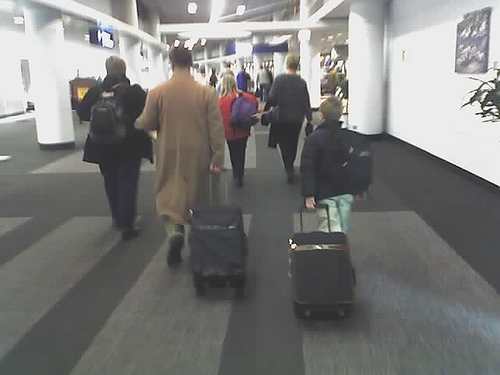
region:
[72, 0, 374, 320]
people carrying suitcases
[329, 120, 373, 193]
a boy carrying a black backpack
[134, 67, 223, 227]
man wearing a long light brown coat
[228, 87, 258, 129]
woman carrying a purple backpack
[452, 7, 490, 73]
a black and white poster on the wall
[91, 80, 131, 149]
a woman carrying a black backpack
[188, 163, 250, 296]
man carrying a black suitcase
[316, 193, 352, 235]
boy wearing light green pants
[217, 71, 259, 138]
a blonde woman wearing a red coat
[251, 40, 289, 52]
a purple banner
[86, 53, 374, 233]
the backs of a group of people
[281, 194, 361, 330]
a black suitcase on wheels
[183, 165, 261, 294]
a gray suitcase on wheels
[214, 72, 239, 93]
the head of a person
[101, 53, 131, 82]
the head of a person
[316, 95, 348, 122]
the head of a person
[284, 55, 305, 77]
the head of a person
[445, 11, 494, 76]
a picture on a wall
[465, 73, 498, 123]
the leaves of a plant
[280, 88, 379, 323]
a boy pulling a suitcase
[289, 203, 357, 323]
a black rolling luggage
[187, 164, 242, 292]
a black rolling luggage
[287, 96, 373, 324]
a child pulling luggage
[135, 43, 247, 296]
a man pulling luggage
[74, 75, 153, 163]
a black winter coat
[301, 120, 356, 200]
a black winter coat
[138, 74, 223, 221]
a long brown coat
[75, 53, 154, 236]
a woman with backpack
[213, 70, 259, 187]
a woman with purple backpack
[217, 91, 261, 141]
a red winter coat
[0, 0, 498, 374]
People walking in the hallway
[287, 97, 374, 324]
The kid dragging a suitcase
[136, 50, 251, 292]
The man dragging a suitcase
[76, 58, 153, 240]
The woman carrying a backpack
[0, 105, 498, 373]
The dark and gray floor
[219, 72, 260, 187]
The woman in red carrying a backpack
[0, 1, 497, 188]
The white painted walls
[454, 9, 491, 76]
A picture on the wall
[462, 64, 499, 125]
A plant inside the hallway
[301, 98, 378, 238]
The kid carrying a black backpack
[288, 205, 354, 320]
a rolling piece of luggage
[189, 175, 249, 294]
a black piece of luggage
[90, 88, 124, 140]
a black backpack being carried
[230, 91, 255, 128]
a purple backpack with black straps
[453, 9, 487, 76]
a piece of wall art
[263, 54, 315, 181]
a person walking away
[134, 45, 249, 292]
a man walking with luggage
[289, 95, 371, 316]
a person walking with luggage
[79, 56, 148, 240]
a person wearing a backpack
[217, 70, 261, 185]
a person wearing a backpack